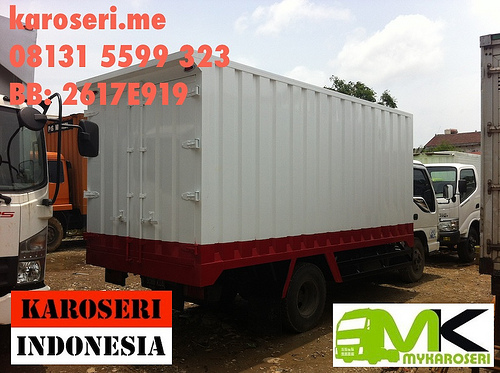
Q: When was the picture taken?
A: During daytime.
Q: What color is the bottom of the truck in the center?
A: Red.